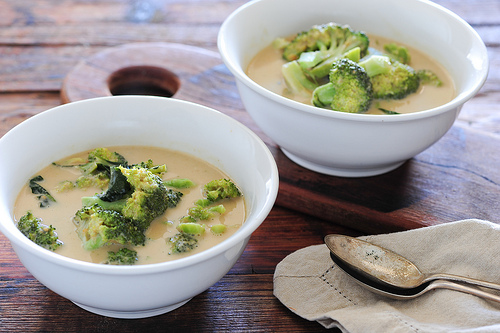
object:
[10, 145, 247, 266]
soup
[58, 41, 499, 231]
wood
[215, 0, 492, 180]
bowl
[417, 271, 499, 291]
handles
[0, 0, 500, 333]
table top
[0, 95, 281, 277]
curves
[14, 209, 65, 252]
broccoli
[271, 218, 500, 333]
napkin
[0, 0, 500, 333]
table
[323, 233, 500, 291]
spoon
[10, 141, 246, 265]
sauce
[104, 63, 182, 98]
hole